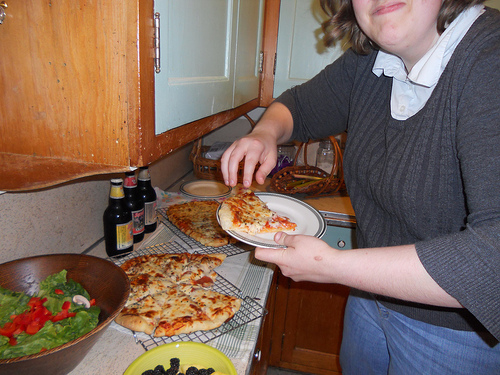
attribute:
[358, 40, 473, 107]
collar — white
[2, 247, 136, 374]
bowl — brown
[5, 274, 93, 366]
salad — green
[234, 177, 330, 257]
white plate — small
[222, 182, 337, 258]
plate — white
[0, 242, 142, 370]
basket — brown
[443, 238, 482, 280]
shirt — grey, woman's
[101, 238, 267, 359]
wire tray — black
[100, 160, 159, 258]
bottles — three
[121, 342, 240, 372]
bowl — yellow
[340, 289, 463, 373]
jeans — blue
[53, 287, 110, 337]
mushroom — white 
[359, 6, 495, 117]
shirt — white 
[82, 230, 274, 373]
tray — black 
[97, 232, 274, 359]
tray — black